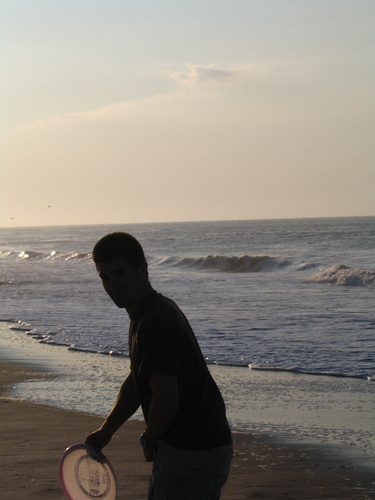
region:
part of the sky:
[227, 17, 292, 53]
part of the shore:
[251, 408, 294, 472]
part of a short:
[190, 458, 222, 493]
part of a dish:
[67, 462, 102, 490]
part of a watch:
[127, 429, 153, 452]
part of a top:
[184, 391, 209, 429]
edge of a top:
[180, 439, 200, 456]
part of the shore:
[277, 383, 324, 433]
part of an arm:
[109, 396, 132, 417]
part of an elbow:
[153, 382, 181, 412]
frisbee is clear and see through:
[43, 437, 127, 498]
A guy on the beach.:
[68, 208, 208, 351]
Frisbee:
[55, 414, 116, 484]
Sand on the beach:
[20, 386, 96, 446]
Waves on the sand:
[40, 377, 121, 431]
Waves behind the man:
[81, 209, 293, 427]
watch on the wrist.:
[139, 419, 159, 470]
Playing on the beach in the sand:
[36, 225, 292, 409]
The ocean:
[225, 259, 360, 364]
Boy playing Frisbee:
[57, 256, 283, 373]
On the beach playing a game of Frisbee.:
[64, 252, 360, 453]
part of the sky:
[215, 8, 261, 46]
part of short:
[176, 456, 200, 478]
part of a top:
[180, 417, 204, 448]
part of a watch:
[129, 428, 149, 444]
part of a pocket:
[209, 455, 231, 476]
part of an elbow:
[157, 393, 182, 417]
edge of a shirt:
[173, 430, 202, 452]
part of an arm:
[112, 392, 130, 411]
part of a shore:
[268, 402, 331, 457]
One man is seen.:
[56, 239, 245, 492]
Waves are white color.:
[174, 240, 297, 329]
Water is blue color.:
[201, 285, 310, 361]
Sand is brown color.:
[7, 417, 54, 494]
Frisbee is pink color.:
[61, 452, 112, 494]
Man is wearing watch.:
[134, 431, 158, 455]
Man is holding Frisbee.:
[29, 310, 210, 498]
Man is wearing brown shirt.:
[139, 337, 212, 430]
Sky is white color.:
[52, 79, 230, 171]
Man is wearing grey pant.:
[148, 463, 229, 499]